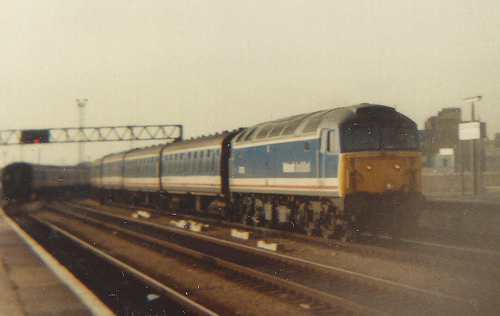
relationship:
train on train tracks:
[81, 90, 418, 260] [88, 196, 491, 314]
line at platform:
[8, 209, 108, 312] [0, 210, 106, 315]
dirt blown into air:
[374, 148, 499, 308] [263, 21, 398, 70]